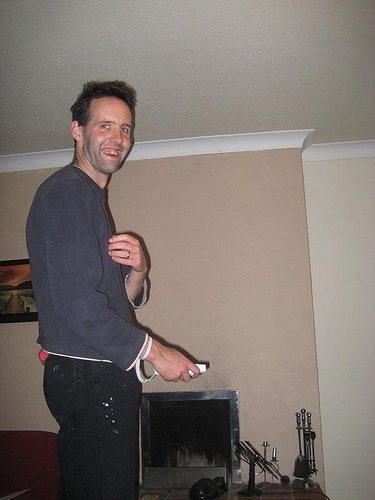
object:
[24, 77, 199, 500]
man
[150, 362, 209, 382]
remote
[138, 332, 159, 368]
wrist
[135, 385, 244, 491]
fireplace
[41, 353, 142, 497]
pants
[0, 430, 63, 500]
couch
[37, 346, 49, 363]
object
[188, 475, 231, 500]
object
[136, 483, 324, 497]
floor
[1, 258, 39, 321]
painting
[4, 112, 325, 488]
wall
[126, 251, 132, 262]
ring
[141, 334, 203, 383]
hand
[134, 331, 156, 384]
strap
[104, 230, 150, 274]
hand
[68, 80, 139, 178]
face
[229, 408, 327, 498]
tools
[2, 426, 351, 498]
chair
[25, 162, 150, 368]
shirt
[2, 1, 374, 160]
ceiling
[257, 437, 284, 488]
candleabra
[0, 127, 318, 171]
moulding